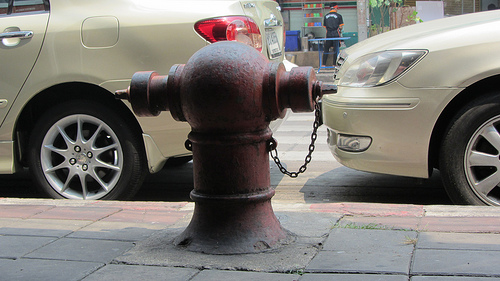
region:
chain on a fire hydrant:
[264, 70, 341, 189]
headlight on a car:
[326, 47, 418, 93]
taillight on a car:
[184, 17, 274, 57]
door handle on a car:
[1, 22, 33, 54]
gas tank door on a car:
[77, 10, 127, 59]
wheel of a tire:
[37, 116, 135, 196]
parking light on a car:
[326, 117, 378, 162]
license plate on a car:
[266, 19, 288, 57]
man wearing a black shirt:
[319, 5, 345, 67]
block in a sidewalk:
[319, 207, 428, 264]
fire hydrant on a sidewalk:
[97, 26, 375, 271]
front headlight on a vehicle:
[328, 37, 437, 100]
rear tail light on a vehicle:
[183, 7, 268, 57]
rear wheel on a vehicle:
[8, 72, 163, 215]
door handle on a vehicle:
[0, 18, 36, 53]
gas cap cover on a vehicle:
[70, 11, 127, 56]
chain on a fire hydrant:
[264, 93, 326, 181]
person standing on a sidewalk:
[317, 0, 350, 70]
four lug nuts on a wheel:
[63, 141, 100, 176]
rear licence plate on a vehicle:
[257, 21, 286, 63]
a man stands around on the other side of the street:
[323, 2, 340, 66]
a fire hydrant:
[130, 38, 322, 269]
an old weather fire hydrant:
[124, 30, 316, 260]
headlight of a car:
[350, 47, 452, 93]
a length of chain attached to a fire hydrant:
[270, 127, 320, 180]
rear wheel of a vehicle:
[30, 88, 131, 205]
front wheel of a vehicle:
[435, 95, 499, 208]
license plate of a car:
[264, 25, 285, 62]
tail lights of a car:
[195, 15, 260, 54]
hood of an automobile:
[345, 9, 499, 52]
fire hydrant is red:
[110, 53, 342, 253]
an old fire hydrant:
[97, 44, 328, 261]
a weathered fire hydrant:
[102, 23, 346, 264]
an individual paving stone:
[316, 221, 420, 275]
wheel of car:
[450, 82, 497, 208]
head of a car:
[337, 51, 439, 87]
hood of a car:
[339, 2, 499, 59]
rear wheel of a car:
[31, 96, 138, 205]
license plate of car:
[265, 22, 288, 62]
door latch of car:
[0, 22, 52, 44]